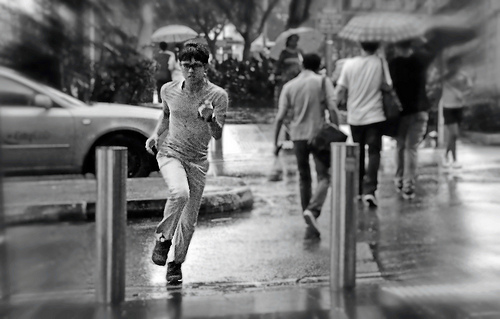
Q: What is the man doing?
A: Running.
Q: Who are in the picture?
A: People.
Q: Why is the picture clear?
A: Its daytime.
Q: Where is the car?
A: By the road.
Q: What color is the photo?
A: Black and white.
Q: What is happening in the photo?
A: It's raining.